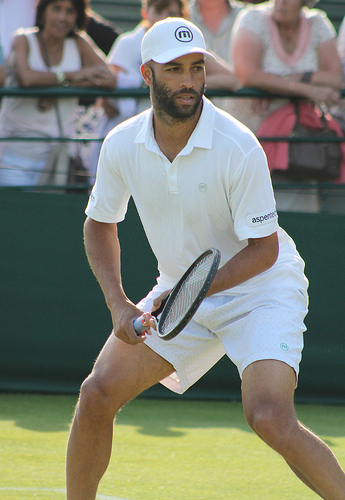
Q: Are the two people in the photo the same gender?
A: No, they are both male and female.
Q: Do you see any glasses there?
A: No, there are no glasses.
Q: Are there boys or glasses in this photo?
A: No, there are no glasses or boys.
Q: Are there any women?
A: Yes, there is a woman.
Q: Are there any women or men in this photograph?
A: Yes, there is a woman.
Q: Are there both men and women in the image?
A: Yes, there are both a woman and a man.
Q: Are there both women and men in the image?
A: Yes, there are both a woman and a man.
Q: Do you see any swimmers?
A: No, there are no swimmers.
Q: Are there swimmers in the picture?
A: No, there are no swimmers.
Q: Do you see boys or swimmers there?
A: No, there are no swimmers or boys.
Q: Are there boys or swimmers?
A: No, there are no swimmers or boys.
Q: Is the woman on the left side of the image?
A: Yes, the woman is on the left of the image.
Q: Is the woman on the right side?
A: No, the woman is on the left of the image.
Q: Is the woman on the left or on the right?
A: The woman is on the left of the image.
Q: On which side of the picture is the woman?
A: The woman is on the left of the image.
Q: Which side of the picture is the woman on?
A: The woman is on the left of the image.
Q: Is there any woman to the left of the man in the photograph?
A: Yes, there is a woman to the left of the man.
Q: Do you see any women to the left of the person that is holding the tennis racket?
A: Yes, there is a woman to the left of the man.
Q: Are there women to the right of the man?
A: No, the woman is to the left of the man.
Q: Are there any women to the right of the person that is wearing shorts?
A: No, the woman is to the left of the man.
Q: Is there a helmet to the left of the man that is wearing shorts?
A: No, there is a woman to the left of the man.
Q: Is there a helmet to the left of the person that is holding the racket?
A: No, there is a woman to the left of the man.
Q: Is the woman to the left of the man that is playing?
A: Yes, the woman is to the left of the man.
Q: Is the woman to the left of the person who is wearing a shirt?
A: Yes, the woman is to the left of the man.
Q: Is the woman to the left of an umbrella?
A: No, the woman is to the left of the man.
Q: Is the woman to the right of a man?
A: No, the woman is to the left of a man.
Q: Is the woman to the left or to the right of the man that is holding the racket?
A: The woman is to the left of the man.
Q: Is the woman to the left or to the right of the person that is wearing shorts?
A: The woman is to the left of the man.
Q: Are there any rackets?
A: Yes, there is a racket.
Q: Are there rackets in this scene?
A: Yes, there is a racket.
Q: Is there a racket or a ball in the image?
A: Yes, there is a racket.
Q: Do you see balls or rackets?
A: Yes, there is a racket.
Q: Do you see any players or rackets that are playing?
A: Yes, the racket is playing.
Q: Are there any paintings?
A: No, there are no paintings.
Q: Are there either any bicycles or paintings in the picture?
A: No, there are no paintings or bicycles.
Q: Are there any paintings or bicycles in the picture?
A: No, there are no paintings or bicycles.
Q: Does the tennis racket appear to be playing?
A: Yes, the tennis racket is playing.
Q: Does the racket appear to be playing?
A: Yes, the racket is playing.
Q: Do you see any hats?
A: Yes, there is a hat.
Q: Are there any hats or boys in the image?
A: Yes, there is a hat.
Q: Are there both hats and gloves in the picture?
A: No, there is a hat but no gloves.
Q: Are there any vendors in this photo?
A: No, there are no vendors.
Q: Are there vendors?
A: No, there are no vendors.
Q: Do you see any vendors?
A: No, there are no vendors.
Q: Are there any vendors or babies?
A: No, there are no vendors or babies.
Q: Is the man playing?
A: Yes, the man is playing.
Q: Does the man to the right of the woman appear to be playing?
A: Yes, the man is playing.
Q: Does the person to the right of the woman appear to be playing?
A: Yes, the man is playing.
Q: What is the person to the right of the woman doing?
A: The man is playing.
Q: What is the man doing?
A: The man is playing.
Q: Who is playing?
A: The man is playing.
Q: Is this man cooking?
A: No, the man is playing.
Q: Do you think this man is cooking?
A: No, the man is playing.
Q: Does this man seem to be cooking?
A: No, the man is playing.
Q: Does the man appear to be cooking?
A: No, the man is playing.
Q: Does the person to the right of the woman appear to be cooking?
A: No, the man is playing.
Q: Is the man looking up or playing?
A: The man is playing.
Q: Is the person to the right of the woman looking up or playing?
A: The man is playing.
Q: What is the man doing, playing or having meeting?
A: The man is playing.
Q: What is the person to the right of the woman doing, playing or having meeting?
A: The man is playing.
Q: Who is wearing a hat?
A: The man is wearing a hat.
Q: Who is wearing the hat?
A: The man is wearing a hat.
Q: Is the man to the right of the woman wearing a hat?
A: Yes, the man is wearing a hat.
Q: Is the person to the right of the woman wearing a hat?
A: Yes, the man is wearing a hat.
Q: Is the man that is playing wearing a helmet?
A: No, the man is wearing a hat.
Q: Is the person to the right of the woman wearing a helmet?
A: No, the man is wearing a hat.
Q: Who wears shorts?
A: The man wears shorts.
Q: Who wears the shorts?
A: The man wears shorts.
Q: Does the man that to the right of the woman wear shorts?
A: Yes, the man wears shorts.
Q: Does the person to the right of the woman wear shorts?
A: Yes, the man wears shorts.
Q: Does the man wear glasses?
A: No, the man wears shorts.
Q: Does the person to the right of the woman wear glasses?
A: No, the man wears shorts.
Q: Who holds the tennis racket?
A: The man holds the tennis racket.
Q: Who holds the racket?
A: The man holds the tennis racket.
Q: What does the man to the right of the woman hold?
A: The man holds the tennis racket.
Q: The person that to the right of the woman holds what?
A: The man holds the tennis racket.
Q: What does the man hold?
A: The man holds the tennis racket.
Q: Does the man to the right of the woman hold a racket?
A: Yes, the man holds a racket.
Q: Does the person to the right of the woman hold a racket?
A: Yes, the man holds a racket.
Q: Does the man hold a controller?
A: No, the man holds a racket.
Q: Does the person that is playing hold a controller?
A: No, the man holds a racket.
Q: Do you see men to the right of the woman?
A: Yes, there is a man to the right of the woman.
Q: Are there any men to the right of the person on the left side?
A: Yes, there is a man to the right of the woman.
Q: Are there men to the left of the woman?
A: No, the man is to the right of the woman.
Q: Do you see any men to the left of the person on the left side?
A: No, the man is to the right of the woman.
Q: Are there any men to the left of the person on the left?
A: No, the man is to the right of the woman.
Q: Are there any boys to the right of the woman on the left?
A: No, there is a man to the right of the woman.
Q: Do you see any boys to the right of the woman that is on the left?
A: No, there is a man to the right of the woman.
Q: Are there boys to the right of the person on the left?
A: No, there is a man to the right of the woman.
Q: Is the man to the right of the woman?
A: Yes, the man is to the right of the woman.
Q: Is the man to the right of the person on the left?
A: Yes, the man is to the right of the woman.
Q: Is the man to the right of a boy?
A: No, the man is to the right of the woman.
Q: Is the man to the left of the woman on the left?
A: No, the man is to the right of the woman.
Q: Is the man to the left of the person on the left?
A: No, the man is to the right of the woman.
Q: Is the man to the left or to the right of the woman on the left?
A: The man is to the right of the woman.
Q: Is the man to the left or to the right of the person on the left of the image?
A: The man is to the right of the woman.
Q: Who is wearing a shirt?
A: The man is wearing a shirt.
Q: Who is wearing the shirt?
A: The man is wearing a shirt.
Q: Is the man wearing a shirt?
A: Yes, the man is wearing a shirt.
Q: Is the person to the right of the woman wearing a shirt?
A: Yes, the man is wearing a shirt.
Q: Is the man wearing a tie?
A: No, the man is wearing a shirt.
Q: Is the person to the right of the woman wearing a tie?
A: No, the man is wearing a shirt.